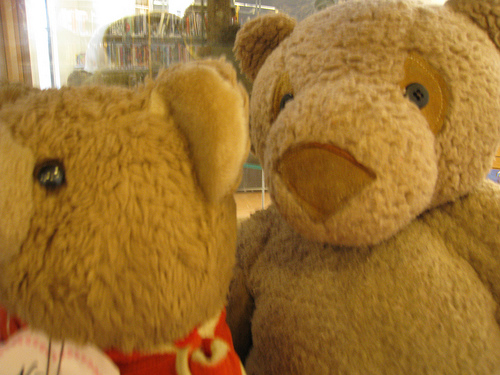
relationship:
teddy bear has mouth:
[224, 2, 499, 373] [297, 210, 349, 248]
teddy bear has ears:
[224, 2, 499, 373] [242, 6, 499, 68]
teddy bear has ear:
[0, 57, 251, 372] [113, 33, 260, 202]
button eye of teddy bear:
[403, 82, 428, 110] [224, 2, 499, 373]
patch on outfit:
[0, 319, 129, 372] [2, 306, 253, 373]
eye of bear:
[32, 150, 69, 194] [0, 49, 253, 372]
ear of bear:
[148, 56, 252, 212] [0, 49, 253, 372]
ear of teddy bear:
[229, 11, 290, 74] [224, 2, 499, 373]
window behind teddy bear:
[4, 0, 344, 191] [224, 2, 499, 373]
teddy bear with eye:
[224, 2, 499, 373] [403, 80, 429, 110]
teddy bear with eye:
[224, 2, 499, 373] [279, 91, 295, 111]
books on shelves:
[118, 9, 197, 57] [99, 36, 207, 49]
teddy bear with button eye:
[224, 2, 499, 373] [402, 81, 432, 113]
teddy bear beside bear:
[224, 2, 499, 373] [0, 49, 253, 372]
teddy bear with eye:
[224, 2, 499, 373] [402, 75, 429, 112]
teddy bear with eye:
[0, 57, 251, 372] [27, 145, 68, 197]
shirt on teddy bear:
[0, 303, 248, 374] [0, 57, 251, 372]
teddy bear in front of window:
[224, 2, 499, 373] [10, 2, 337, 227]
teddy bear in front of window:
[0, 57, 251, 372] [10, 2, 337, 227]